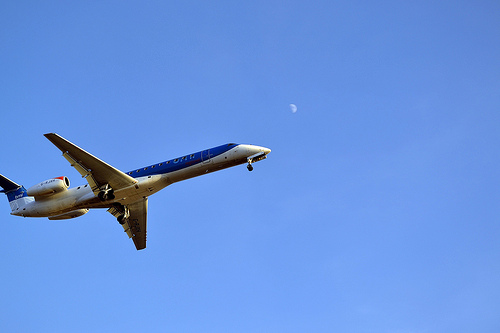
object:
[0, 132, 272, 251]
airplane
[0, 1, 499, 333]
sky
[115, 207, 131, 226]
landing gear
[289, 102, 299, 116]
moon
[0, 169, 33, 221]
tail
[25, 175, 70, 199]
jets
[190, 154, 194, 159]
windows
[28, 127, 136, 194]
wings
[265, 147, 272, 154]
nose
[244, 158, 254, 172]
landing gear